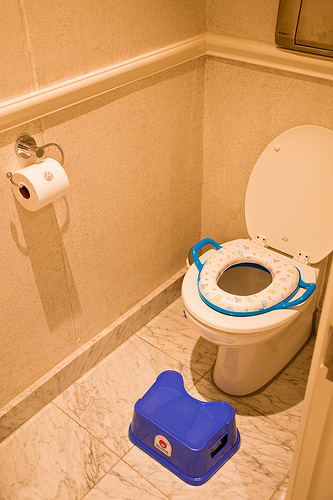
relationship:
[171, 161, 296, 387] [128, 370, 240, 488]
toilet white stepstool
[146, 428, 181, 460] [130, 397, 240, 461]
sticker on stepstool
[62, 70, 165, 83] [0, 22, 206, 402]
molding on wall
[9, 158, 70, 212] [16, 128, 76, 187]
tissue on dispenser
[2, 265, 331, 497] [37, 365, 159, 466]
tiles on floor